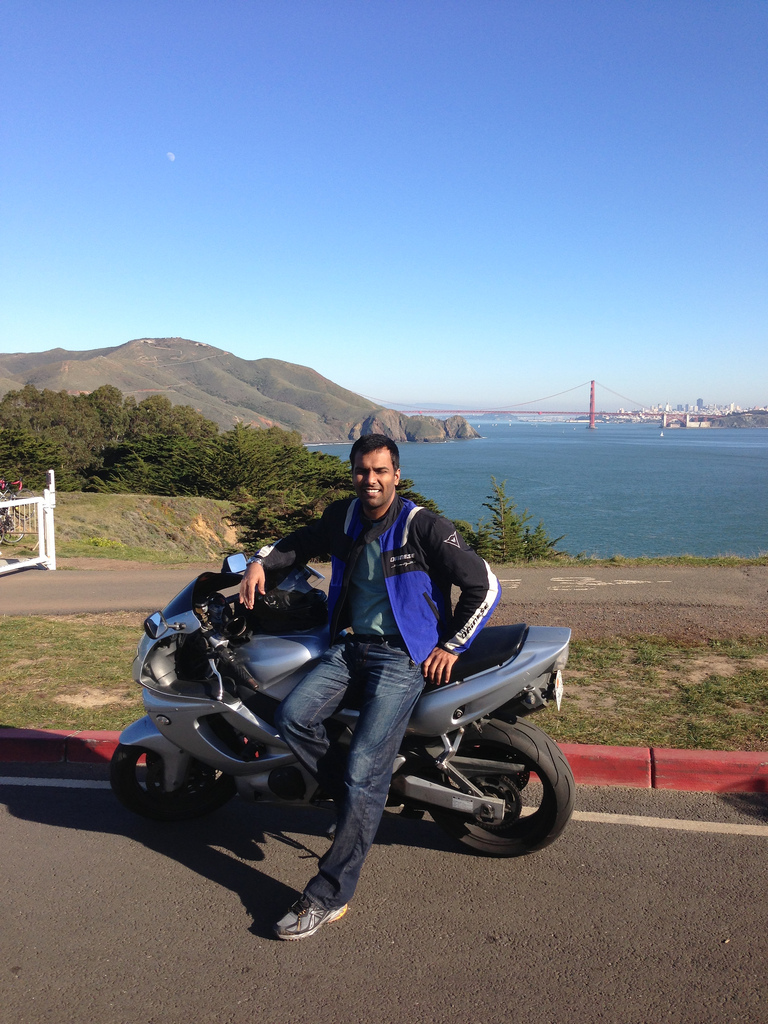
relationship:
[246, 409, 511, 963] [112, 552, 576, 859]
man on bike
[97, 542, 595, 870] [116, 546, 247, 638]
bike has a windshield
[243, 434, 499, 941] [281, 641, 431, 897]
man wearing jeans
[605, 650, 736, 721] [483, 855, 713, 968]
grass on road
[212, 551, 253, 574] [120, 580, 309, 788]
rearview mirrors on bike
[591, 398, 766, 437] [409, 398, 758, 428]
san francisco on horizon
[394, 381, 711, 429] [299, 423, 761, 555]
bridge spanning strait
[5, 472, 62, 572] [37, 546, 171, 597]
gate to road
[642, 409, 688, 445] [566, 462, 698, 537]
boat on water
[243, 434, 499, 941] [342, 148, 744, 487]
man squints into sunlight